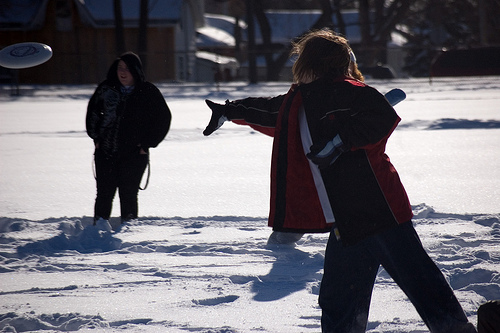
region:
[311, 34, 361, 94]
girl has brown hair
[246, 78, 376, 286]
girl has red coat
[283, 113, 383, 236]
white stripe on coat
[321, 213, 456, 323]
girl has black pants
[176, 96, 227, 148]
black and white gloves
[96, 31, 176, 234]
person has black coat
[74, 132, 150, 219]
person has black pants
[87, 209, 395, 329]
people walking in deep snow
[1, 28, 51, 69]
white frisbee in air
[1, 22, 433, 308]
girl is throwing frisbee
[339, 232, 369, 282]
edge of a coat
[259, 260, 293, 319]
aprt fo a shade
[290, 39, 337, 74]
Person has brown hair.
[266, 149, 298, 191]
Person wearing red and black coat.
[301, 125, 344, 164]
Person wearing black and white gloves.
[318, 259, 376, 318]
Person wearing black pants.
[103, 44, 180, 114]
Person has black hood up on head.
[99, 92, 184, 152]
Person wearing black coat.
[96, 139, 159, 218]
Person wearing black pants.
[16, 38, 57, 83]
Frisbee flying thru air.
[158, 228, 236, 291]
Ground is covered in snow.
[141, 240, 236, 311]
Snow on ground is white.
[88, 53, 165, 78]
person with black hood on their head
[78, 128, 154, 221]
person wearing black pants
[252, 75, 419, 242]
person wearing a red jacket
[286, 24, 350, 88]
person with red hair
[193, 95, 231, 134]
person with a glove on their hand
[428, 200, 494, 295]
tracks in the snow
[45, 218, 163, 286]
foot prints in the snow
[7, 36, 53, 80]
frisbee in the sky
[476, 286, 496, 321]
backpack on the ground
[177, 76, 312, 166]
person with there arm out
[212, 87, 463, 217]
this is a woman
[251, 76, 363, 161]
this is a jacket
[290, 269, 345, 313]
this is a pair of pants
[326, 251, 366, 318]
the pants are black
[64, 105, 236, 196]
this is a jacket that is black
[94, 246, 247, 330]
this is a footprint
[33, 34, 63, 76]
this is a frisbee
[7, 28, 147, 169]
the frisbee is plastic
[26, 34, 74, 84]
the frisbee is white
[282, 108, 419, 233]
this is a glove